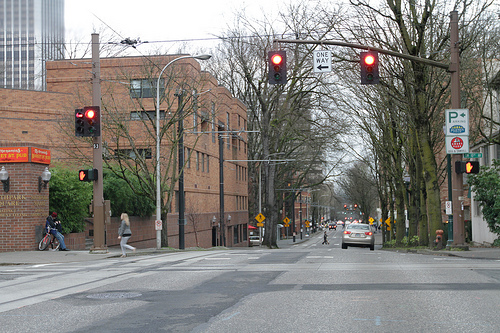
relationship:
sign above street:
[312, 47, 333, 75] [55, 220, 490, 331]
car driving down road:
[332, 210, 385, 265] [0, 218, 484, 331]